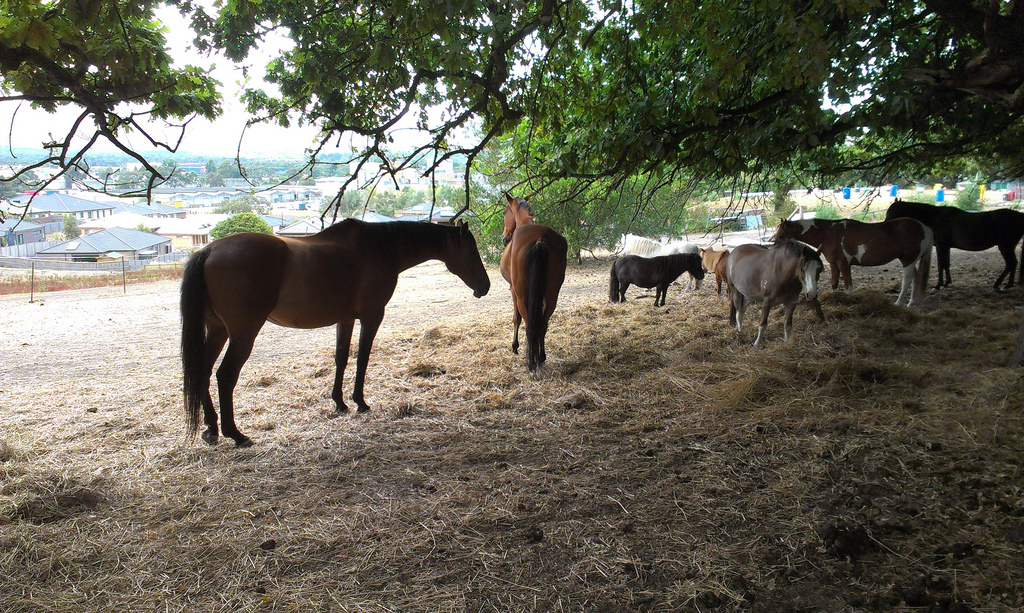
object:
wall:
[14, 226, 43, 244]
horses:
[500, 190, 569, 373]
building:
[2, 206, 66, 271]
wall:
[2, 241, 68, 257]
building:
[8, 226, 173, 272]